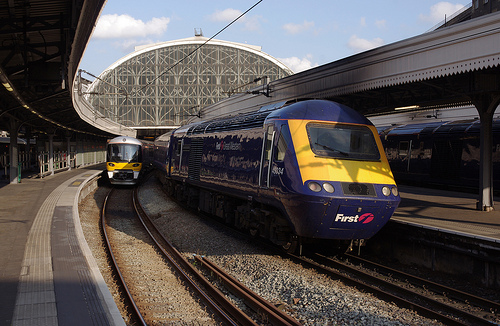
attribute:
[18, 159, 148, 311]
platform — empty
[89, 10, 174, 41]
cloud — white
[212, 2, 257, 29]
cloud — white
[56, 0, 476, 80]
sky — blue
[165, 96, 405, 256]
engine — blue, yellow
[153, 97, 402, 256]
train — blue and yellow, purple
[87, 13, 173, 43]
clouds — white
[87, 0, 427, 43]
sky — blue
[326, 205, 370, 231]
first — word